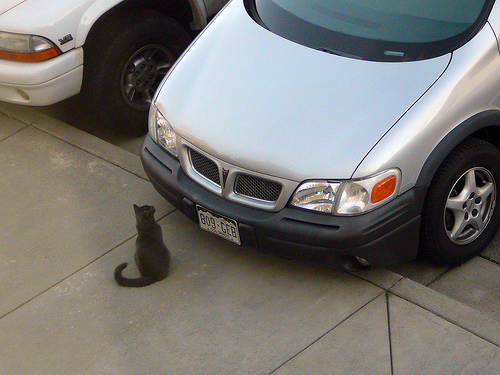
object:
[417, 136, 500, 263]
tire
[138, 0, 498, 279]
automobile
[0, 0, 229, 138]
automobile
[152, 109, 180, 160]
headlights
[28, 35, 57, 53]
headlights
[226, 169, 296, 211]
grill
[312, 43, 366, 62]
wiper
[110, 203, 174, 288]
cat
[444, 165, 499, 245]
rim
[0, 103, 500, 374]
sidewalk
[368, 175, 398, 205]
turn signal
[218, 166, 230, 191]
logo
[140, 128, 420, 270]
bumper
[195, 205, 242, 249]
license plate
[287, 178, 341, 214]
headlight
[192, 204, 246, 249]
809 geb